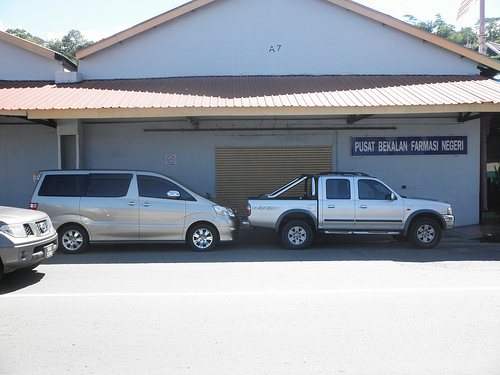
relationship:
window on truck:
[352, 176, 395, 205] [241, 144, 464, 264]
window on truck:
[318, 174, 357, 203] [241, 144, 464, 264]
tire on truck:
[409, 215, 443, 250] [241, 144, 464, 264]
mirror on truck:
[386, 189, 401, 203] [241, 144, 464, 264]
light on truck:
[444, 207, 455, 217] [241, 144, 464, 264]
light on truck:
[242, 202, 255, 216] [241, 144, 464, 264]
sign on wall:
[343, 130, 476, 158] [79, 126, 498, 228]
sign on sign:
[350, 135, 468, 157] [343, 130, 476, 158]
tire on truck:
[404, 209, 448, 248] [241, 144, 464, 264]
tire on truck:
[270, 212, 317, 251] [241, 144, 464, 264]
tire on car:
[182, 218, 220, 257] [16, 162, 238, 255]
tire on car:
[51, 220, 92, 255] [16, 162, 238, 255]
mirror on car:
[165, 186, 186, 200] [16, 162, 238, 255]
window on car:
[134, 172, 195, 204] [16, 162, 238, 255]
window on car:
[38, 171, 134, 207] [16, 162, 238, 255]